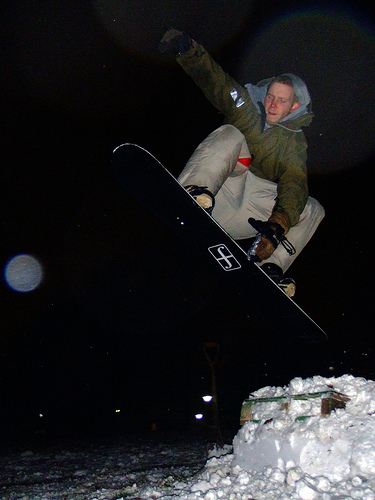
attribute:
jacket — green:
[172, 39, 313, 231]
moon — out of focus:
[0, 250, 46, 293]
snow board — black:
[70, 125, 315, 433]